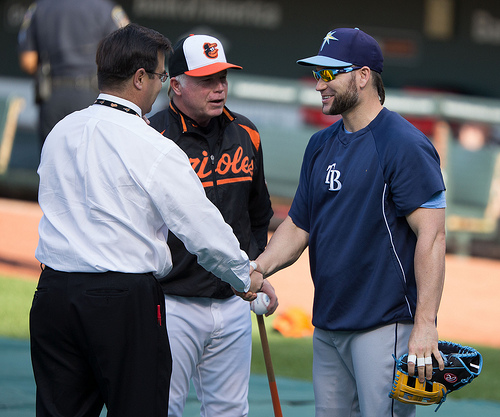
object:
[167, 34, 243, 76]
cap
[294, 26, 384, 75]
hat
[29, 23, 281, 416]
man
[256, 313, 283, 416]
bat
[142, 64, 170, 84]
glasses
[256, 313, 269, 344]
handle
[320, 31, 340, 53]
design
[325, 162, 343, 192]
logo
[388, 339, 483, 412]
glove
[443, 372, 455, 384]
logo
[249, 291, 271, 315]
baseball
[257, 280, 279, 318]
hand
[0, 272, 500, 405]
grass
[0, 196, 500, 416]
field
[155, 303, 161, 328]
pen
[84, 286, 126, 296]
pocket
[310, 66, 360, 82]
sunglasses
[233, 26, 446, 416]
player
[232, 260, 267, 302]
hand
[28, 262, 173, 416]
pants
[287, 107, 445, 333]
shirt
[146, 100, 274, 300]
jacket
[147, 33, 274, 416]
man